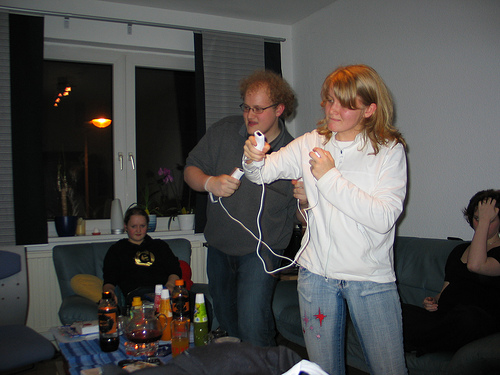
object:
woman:
[102, 206, 211, 323]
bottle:
[96, 291, 121, 351]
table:
[47, 314, 220, 375]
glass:
[169, 317, 191, 356]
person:
[242, 63, 410, 374]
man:
[182, 69, 305, 344]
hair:
[237, 70, 300, 124]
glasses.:
[239, 100, 282, 114]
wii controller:
[218, 167, 245, 199]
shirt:
[184, 115, 297, 255]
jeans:
[203, 243, 284, 352]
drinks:
[192, 292, 210, 351]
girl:
[396, 187, 500, 355]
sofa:
[269, 232, 500, 374]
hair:
[316, 63, 411, 158]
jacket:
[239, 125, 409, 287]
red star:
[312, 306, 328, 328]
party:
[1, 2, 499, 373]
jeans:
[294, 262, 410, 375]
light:
[87, 117, 112, 130]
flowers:
[161, 174, 174, 185]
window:
[0, 7, 285, 250]